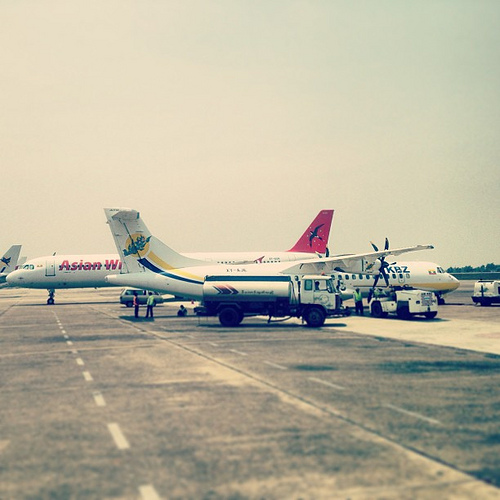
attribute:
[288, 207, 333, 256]
tail fin — pink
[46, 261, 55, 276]
door — white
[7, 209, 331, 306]
plane — large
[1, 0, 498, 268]
skies — clear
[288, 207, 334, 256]
stabilizer — red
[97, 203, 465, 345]
plane — large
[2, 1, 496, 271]
sky — overcast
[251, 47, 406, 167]
sky — bright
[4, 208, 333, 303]
airplane — white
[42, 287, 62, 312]
wheel — black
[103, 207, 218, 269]
tail fin — white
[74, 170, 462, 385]
airplane — white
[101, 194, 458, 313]
airplane — being fueled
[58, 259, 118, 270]
writing — red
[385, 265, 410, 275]
writing — red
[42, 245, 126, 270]
writing — red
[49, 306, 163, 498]
lines — white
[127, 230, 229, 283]
stripe — yellow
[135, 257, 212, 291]
stripe — blue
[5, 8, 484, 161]
sky — blue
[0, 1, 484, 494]
day — clear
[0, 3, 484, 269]
cloud — white